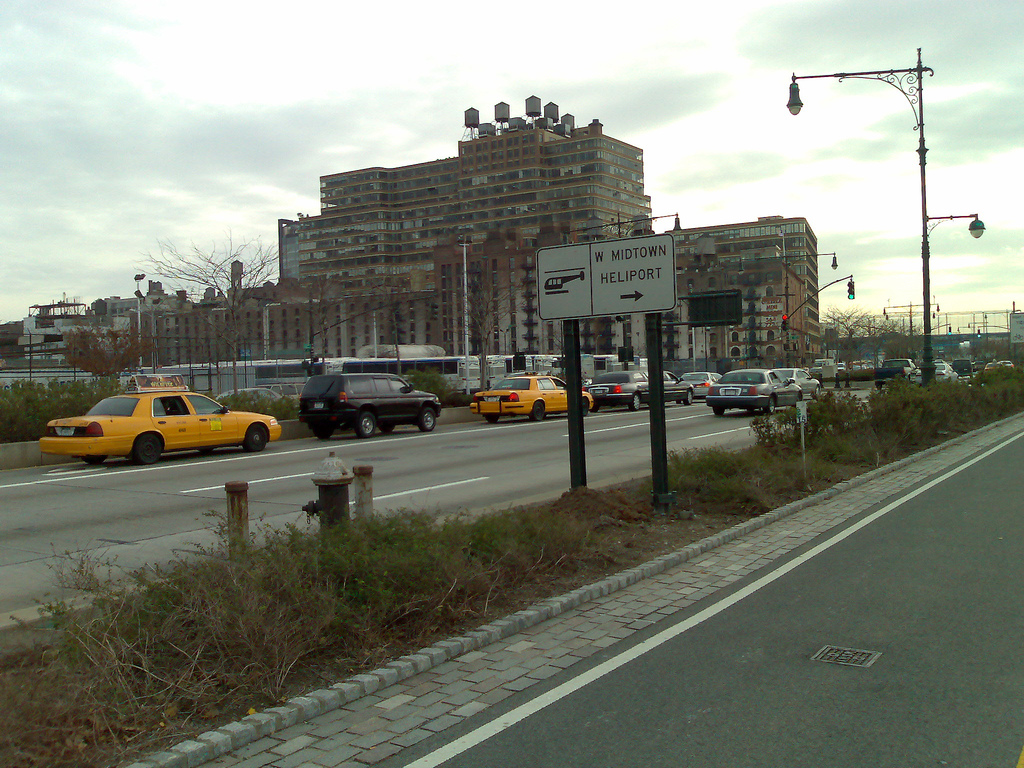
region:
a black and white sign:
[535, 241, 673, 319]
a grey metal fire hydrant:
[302, 452, 351, 525]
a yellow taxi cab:
[40, 381, 278, 454]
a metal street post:
[219, 478, 252, 564]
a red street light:
[777, 307, 794, 327]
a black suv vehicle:
[298, 367, 439, 429]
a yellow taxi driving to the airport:
[41, 371, 279, 466]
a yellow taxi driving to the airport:
[473, 371, 591, 420]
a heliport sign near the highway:
[531, 232, 677, 324]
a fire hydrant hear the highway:
[305, 457, 356, 544]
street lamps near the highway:
[787, 48, 985, 393]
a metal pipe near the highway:
[223, 483, 255, 563]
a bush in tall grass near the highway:
[796, 388, 872, 446]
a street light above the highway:
[847, 282, 855, 301]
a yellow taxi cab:
[33, 331, 274, 505]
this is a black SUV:
[286, 342, 455, 475]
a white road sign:
[495, 208, 726, 512]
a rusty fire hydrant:
[280, 421, 375, 595]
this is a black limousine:
[573, 347, 703, 455]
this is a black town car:
[689, 341, 810, 444]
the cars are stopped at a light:
[10, 329, 864, 533]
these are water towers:
[434, 81, 589, 179]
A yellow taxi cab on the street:
[95, 401, 220, 443]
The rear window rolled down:
[167, 402, 181, 410]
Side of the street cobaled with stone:
[409, 696, 464, 722]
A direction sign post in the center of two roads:
[590, 247, 661, 308]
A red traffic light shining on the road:
[780, 312, 791, 322]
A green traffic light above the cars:
[846, 293, 856, 300]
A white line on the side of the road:
[562, 681, 579, 691]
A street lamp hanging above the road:
[973, 225, 983, 238]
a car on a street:
[56, 370, 279, 460]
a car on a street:
[321, 369, 448, 445]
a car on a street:
[474, 358, 602, 415]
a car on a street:
[583, 356, 666, 398]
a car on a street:
[707, 357, 790, 414]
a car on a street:
[773, 356, 830, 402]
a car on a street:
[668, 361, 720, 403]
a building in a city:
[545, 209, 825, 369]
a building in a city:
[285, 93, 641, 341]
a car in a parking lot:
[211, 369, 289, 420]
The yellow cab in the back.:
[27, 376, 285, 454]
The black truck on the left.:
[299, 354, 446, 440]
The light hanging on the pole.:
[923, 203, 993, 254]